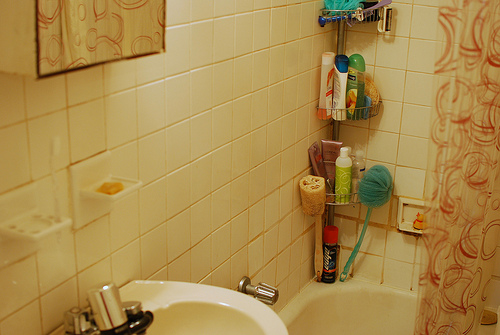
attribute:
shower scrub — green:
[340, 165, 399, 283]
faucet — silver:
[73, 272, 144, 330]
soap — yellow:
[97, 178, 126, 197]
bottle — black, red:
[319, 222, 341, 284]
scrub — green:
[341, 155, 394, 279]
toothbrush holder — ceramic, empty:
[7, 179, 85, 274]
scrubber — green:
[333, 157, 392, 282]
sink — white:
[48, 279, 288, 334]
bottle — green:
[325, 55, 354, 127]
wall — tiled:
[8, 7, 393, 308]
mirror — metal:
[63, 6, 155, 41]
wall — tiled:
[153, 13, 300, 243]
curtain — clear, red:
[411, 2, 496, 330]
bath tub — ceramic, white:
[278, 269, 455, 333]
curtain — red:
[418, 47, 499, 219]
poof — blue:
[353, 162, 397, 292]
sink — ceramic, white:
[126, 280, 267, 333]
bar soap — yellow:
[97, 176, 126, 198]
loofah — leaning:
[292, 168, 332, 286]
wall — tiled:
[5, 2, 346, 332]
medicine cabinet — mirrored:
[33, 1, 171, 74]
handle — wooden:
[310, 219, 332, 277]